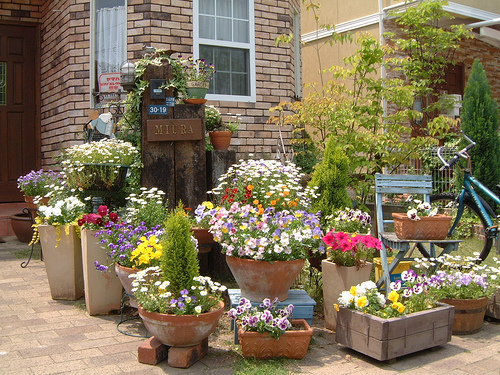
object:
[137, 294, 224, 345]
planter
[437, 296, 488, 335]
barrel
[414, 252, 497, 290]
flowers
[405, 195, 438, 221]
flowers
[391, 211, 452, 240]
planter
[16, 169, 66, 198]
flowers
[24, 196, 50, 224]
planter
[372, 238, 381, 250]
flower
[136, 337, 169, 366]
brick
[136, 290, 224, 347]
pot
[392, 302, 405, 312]
flower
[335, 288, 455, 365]
planter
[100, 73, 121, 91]
sign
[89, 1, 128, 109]
window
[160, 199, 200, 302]
bush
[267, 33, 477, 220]
bush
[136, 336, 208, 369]
brick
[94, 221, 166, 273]
flowers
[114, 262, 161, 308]
planter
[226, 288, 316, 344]
stool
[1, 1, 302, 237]
house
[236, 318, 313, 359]
pot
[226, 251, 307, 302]
pot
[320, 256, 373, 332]
pot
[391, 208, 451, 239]
pot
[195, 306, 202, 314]
flower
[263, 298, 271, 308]
flower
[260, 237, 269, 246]
flower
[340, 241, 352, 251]
flower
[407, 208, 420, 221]
flower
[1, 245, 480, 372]
sidewalk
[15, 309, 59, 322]
brick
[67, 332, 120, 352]
brick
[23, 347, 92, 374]
brick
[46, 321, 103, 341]
brick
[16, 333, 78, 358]
brick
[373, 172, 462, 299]
chair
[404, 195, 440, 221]
pansies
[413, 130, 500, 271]
bicycle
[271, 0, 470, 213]
bush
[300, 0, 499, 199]
home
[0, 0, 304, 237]
home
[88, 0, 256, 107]
windows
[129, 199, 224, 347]
planter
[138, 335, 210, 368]
bricks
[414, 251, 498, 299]
pansies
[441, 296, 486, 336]
barrel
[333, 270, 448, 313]
flowers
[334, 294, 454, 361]
container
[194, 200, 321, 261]
pansies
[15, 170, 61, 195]
flowers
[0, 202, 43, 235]
stand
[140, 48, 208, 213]
display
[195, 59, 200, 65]
flower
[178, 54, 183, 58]
flower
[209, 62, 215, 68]
flower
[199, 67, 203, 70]
flower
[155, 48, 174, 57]
flower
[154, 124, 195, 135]
miura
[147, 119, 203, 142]
sign